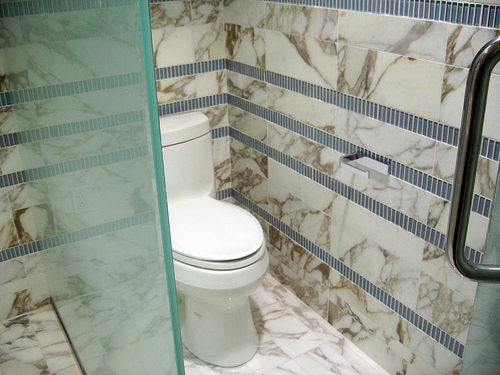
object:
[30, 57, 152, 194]
walls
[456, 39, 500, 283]
handle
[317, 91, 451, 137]
stripes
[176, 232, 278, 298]
seat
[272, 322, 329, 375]
floor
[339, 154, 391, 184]
holder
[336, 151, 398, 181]
paper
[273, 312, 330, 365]
tile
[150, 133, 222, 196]
tank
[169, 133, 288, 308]
toilet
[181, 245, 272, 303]
bowl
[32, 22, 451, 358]
bathroom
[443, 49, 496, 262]
bar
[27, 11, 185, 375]
glass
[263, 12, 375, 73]
marble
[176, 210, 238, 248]
lid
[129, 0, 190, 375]
divider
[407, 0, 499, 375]
door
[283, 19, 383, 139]
wall